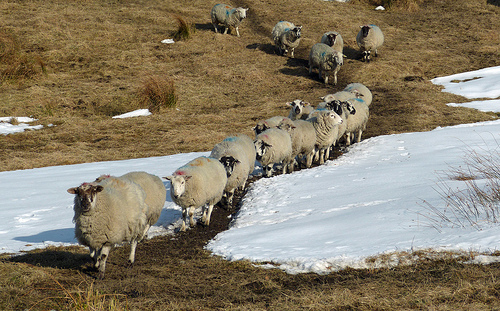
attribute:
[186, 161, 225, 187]
sheep — fluffy, white, black, line, in front, last, out of line, second, here, big, yellow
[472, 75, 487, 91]
snow — path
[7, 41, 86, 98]
grass — green, tuft, parched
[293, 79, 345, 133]
head — large